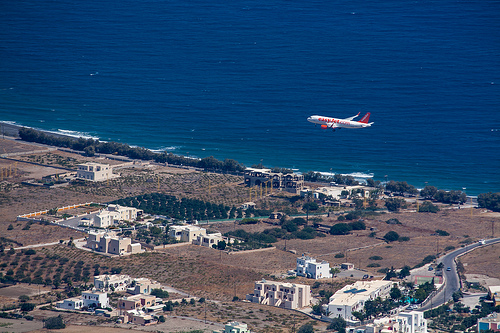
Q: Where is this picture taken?
A: A beach town.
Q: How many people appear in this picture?
A: Zero.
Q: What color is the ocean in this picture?
A: Blue.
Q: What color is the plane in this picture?
A: White.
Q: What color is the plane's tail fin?
A: Red.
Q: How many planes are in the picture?
A: One.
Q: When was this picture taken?
A: Daytime.